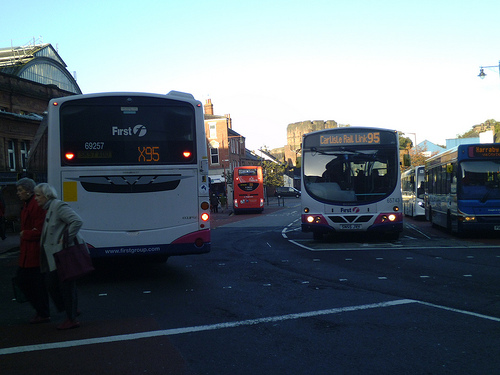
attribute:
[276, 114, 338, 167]
building — is old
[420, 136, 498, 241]
bus — Blue 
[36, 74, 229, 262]
bus — white 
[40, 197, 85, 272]
coat — white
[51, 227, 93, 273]
bag — red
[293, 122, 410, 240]
bus — white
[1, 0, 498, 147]
sky — daytime 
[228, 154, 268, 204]
bus — double decker 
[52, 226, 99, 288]
handbag — black 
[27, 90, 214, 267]
bus — one , white, mass transit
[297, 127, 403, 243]
bus — one 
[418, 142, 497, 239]
bus — one 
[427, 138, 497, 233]
bus — blue , mass , transit 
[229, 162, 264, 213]
bus — red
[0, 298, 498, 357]
line — white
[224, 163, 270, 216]
bus — red, two-level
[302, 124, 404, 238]
bus — blue , mass , transit , public , white 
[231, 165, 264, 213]
bus — red 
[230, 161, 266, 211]
bus — blue , mass , transit 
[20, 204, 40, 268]
jacket — is red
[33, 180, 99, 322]
woman — elder, one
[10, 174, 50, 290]
woman — elder, one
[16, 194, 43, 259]
coat — red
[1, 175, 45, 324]
elderly woman — elderly 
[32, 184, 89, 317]
elderly woman — elderly 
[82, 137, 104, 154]
white numbers — white 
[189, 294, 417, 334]
white line — white 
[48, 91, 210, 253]
bus — blue , mass , transit 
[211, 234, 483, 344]
marked area — marked 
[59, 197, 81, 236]
person's arm — person's 